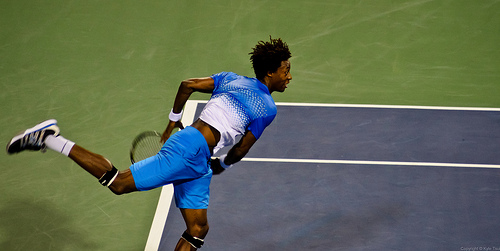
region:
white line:
[385, 147, 415, 174]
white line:
[292, 141, 353, 182]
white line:
[280, 117, 410, 181]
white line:
[314, 124, 415, 221]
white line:
[314, 125, 452, 165]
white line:
[322, 155, 357, 212]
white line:
[342, 145, 430, 187]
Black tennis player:
[26, 42, 313, 228]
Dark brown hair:
[253, 32, 297, 92]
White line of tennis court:
[250, 148, 499, 179]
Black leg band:
[95, 162, 123, 191]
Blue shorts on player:
[114, 142, 225, 205]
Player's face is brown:
[277, 60, 290, 94]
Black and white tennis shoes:
[5, 115, 76, 154]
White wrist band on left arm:
[170, 107, 188, 122]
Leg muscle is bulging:
[188, 207, 208, 231]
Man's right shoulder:
[252, 91, 287, 118]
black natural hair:
[246, 35, 291, 85]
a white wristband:
[165, 105, 182, 121]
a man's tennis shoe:
[2, 115, 62, 150]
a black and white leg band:
[175, 230, 205, 245]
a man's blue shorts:
[120, 121, 216, 207]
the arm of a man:
[150, 66, 226, 117]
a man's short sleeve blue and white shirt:
[198, 72, 276, 161]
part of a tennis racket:
[125, 125, 164, 162]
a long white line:
[216, 152, 498, 172]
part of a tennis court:
[0, 0, 495, 111]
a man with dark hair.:
[244, 30, 309, 105]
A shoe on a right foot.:
[0, 108, 62, 167]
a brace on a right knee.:
[93, 159, 128, 191]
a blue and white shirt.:
[196, 50, 283, 171]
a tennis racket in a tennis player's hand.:
[121, 124, 178, 171]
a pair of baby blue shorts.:
[118, 125, 213, 232]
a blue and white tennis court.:
[139, 96, 494, 249]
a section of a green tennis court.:
[3, 0, 186, 250]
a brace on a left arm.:
[161, 101, 200, 125]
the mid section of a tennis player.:
[181, 119, 225, 159]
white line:
[300, 145, 392, 206]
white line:
[261, 121, 361, 198]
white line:
[335, 121, 369, 193]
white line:
[360, 112, 402, 212]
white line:
[300, 108, 357, 188]